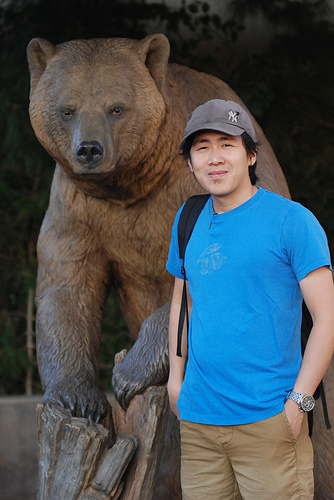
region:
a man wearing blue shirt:
[144, 86, 327, 498]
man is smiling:
[167, 98, 292, 253]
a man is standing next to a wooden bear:
[9, 29, 331, 494]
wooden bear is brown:
[7, 10, 196, 434]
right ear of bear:
[130, 28, 180, 92]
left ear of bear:
[19, 31, 66, 93]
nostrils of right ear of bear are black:
[72, 135, 105, 167]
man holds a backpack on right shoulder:
[145, 99, 327, 372]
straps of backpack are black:
[306, 395, 329, 438]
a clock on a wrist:
[283, 380, 324, 428]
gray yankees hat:
[170, 96, 265, 146]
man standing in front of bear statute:
[158, 100, 333, 496]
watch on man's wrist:
[284, 387, 316, 412]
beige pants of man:
[171, 410, 319, 499]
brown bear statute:
[13, 27, 316, 497]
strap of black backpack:
[164, 185, 211, 268]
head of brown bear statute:
[14, 31, 184, 189]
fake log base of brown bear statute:
[30, 382, 179, 498]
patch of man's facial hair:
[209, 176, 224, 187]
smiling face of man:
[176, 128, 257, 195]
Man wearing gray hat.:
[186, 96, 255, 157]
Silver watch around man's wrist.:
[288, 386, 317, 424]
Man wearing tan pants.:
[201, 448, 275, 470]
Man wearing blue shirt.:
[207, 371, 235, 395]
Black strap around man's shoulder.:
[178, 197, 244, 289]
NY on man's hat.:
[223, 102, 248, 143]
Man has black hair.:
[237, 135, 271, 194]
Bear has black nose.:
[75, 133, 108, 177]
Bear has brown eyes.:
[54, 90, 139, 129]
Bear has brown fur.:
[64, 145, 143, 264]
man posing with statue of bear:
[4, 10, 324, 489]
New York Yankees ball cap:
[177, 100, 259, 148]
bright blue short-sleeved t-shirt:
[164, 189, 329, 426]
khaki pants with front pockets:
[173, 397, 319, 498]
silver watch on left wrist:
[280, 384, 322, 419]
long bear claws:
[43, 387, 117, 424]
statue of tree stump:
[27, 380, 195, 494]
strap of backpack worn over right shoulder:
[166, 189, 210, 351]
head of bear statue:
[12, 33, 180, 192]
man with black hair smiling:
[180, 98, 264, 198]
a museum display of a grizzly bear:
[26, 32, 172, 413]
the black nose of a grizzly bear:
[75, 139, 102, 168]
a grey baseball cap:
[181, 97, 258, 146]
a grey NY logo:
[227, 109, 239, 123]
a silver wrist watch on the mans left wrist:
[288, 387, 315, 412]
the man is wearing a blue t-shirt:
[166, 187, 332, 425]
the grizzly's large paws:
[42, 374, 109, 426]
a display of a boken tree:
[35, 403, 178, 497]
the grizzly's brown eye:
[108, 101, 126, 119]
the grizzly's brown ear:
[141, 33, 170, 89]